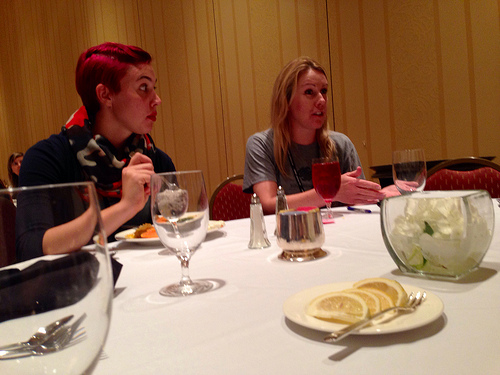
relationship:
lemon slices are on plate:
[312, 282, 405, 326] [285, 278, 445, 339]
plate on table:
[285, 278, 445, 339] [1, 192, 499, 373]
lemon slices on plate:
[312, 282, 405, 326] [285, 278, 445, 339]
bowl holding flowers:
[380, 187, 496, 281] [400, 201, 477, 270]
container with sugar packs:
[380, 187, 496, 281] [400, 201, 477, 270]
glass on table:
[389, 151, 430, 199] [1, 192, 499, 373]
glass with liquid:
[309, 158, 346, 225] [313, 164, 342, 197]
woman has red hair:
[15, 41, 180, 259] [74, 44, 153, 121]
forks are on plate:
[326, 293, 429, 349] [285, 278, 445, 339]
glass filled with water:
[150, 174, 206, 248] [156, 217, 207, 251]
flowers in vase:
[400, 201, 477, 270] [380, 187, 496, 281]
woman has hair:
[15, 41, 180, 259] [74, 44, 153, 121]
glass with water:
[150, 174, 206, 248] [156, 217, 207, 251]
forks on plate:
[326, 293, 429, 349] [285, 278, 445, 339]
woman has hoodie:
[15, 41, 180, 259] [16, 131, 172, 262]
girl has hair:
[269, 56, 340, 174] [271, 56, 338, 171]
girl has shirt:
[269, 56, 340, 174] [244, 126, 360, 210]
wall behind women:
[2, 0, 499, 196] [15, 45, 366, 259]